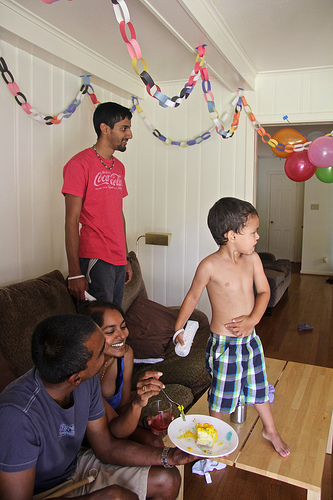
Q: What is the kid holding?
A: A console.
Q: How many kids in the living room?
A: One.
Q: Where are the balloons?
A: At the entrance.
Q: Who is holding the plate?
A: A man.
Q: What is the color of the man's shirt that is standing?
A: Red.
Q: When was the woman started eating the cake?
A: Earlier.